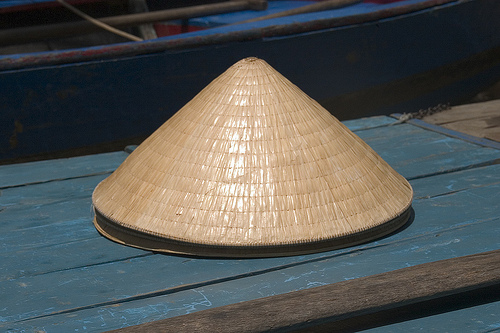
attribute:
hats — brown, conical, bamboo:
[81, 50, 425, 266]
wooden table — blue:
[2, 112, 498, 330]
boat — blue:
[4, 2, 497, 160]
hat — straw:
[141, 88, 413, 215]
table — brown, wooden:
[19, 102, 494, 319]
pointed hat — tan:
[95, 52, 412, 259]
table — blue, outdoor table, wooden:
[0, 107, 496, 330]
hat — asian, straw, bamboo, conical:
[87, 55, 418, 252]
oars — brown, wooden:
[410, 264, 467, 308]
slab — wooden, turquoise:
[41, 99, 468, 327]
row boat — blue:
[0, 2, 496, 158]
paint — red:
[0, 1, 497, 157]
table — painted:
[73, 235, 152, 333]